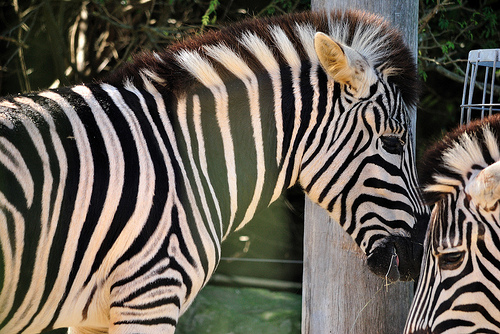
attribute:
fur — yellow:
[328, 60, 346, 79]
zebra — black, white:
[0, 23, 437, 320]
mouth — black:
[360, 238, 424, 279]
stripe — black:
[48, 85, 113, 331]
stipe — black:
[211, 65, 263, 226]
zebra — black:
[405, 104, 498, 332]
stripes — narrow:
[304, 113, 418, 264]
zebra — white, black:
[395, 116, 497, 332]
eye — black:
[375, 132, 407, 157]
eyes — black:
[372, 121, 417, 146]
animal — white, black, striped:
[1, 7, 453, 332]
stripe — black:
[208, 58, 256, 229]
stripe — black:
[60, 146, 124, 270]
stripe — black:
[5, 133, 52, 272]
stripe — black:
[438, 278, 491, 313]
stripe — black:
[357, 171, 403, 208]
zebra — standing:
[2, 5, 449, 312]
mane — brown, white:
[419, 125, 499, 201]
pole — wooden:
[300, 0, 418, 332]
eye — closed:
[436, 246, 466, 268]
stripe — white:
[42, 87, 164, 289]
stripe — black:
[207, 52, 259, 220]